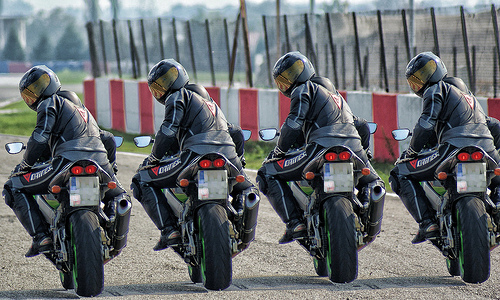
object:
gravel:
[126, 257, 179, 298]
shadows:
[3, 271, 479, 298]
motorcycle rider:
[6, 60, 136, 297]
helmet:
[142, 58, 191, 101]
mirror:
[239, 129, 252, 141]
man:
[388, 51, 500, 242]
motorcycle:
[386, 127, 498, 281]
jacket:
[271, 76, 367, 150]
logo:
[329, 93, 342, 111]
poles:
[488, 4, 496, 98]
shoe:
[22, 236, 54, 258]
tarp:
[78, 62, 498, 184]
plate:
[451, 162, 485, 195]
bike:
[134, 128, 258, 290]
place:
[195, 168, 230, 201]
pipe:
[367, 184, 383, 238]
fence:
[85, 2, 499, 98]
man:
[4, 64, 116, 255]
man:
[254, 52, 381, 243]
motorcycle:
[257, 121, 382, 281]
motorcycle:
[4, 136, 128, 291]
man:
[131, 57, 254, 252]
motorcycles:
[2, 125, 480, 299]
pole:
[373, 10, 392, 92]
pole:
[324, 12, 335, 90]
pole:
[221, 17, 235, 80]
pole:
[202, 17, 218, 84]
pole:
[96, 20, 109, 74]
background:
[1, 0, 497, 100]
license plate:
[195, 169, 228, 200]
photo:
[3, 0, 500, 300]